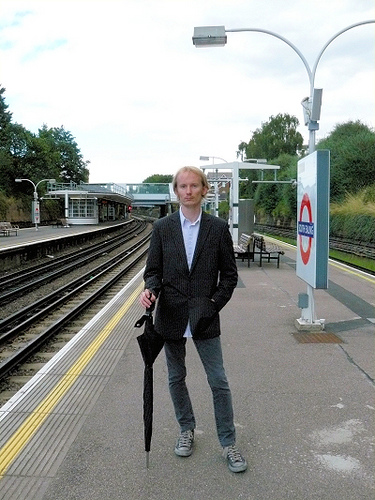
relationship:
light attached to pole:
[189, 24, 232, 51] [225, 18, 373, 99]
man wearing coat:
[137, 161, 258, 473] [140, 209, 240, 343]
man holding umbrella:
[137, 161, 258, 473] [133, 290, 169, 471]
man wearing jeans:
[137, 161, 258, 473] [160, 328, 238, 451]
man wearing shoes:
[137, 161, 258, 473] [172, 423, 247, 479]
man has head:
[137, 161, 258, 473] [170, 164, 208, 213]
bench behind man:
[230, 230, 259, 268] [137, 161, 258, 473]